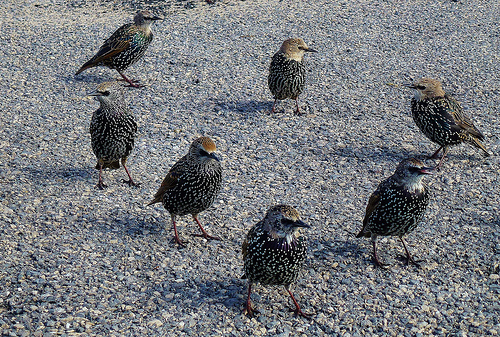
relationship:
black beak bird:
[297, 41, 318, 57] [271, 29, 327, 119]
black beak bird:
[400, 79, 430, 94] [397, 66, 491, 150]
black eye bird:
[297, 41, 318, 57] [271, 29, 327, 119]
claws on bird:
[266, 94, 308, 119] [271, 29, 327, 119]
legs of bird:
[266, 94, 308, 119] [271, 29, 327, 119]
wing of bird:
[75, 34, 121, 76] [90, 9, 174, 83]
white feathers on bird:
[254, 220, 288, 239] [235, 202, 315, 272]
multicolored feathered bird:
[91, 108, 140, 160] [82, 94, 138, 166]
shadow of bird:
[211, 97, 273, 119] [246, 21, 319, 120]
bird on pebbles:
[263, 35, 311, 111] [259, 129, 319, 167]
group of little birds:
[60, 26, 465, 269] [106, 20, 479, 131]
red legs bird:
[272, 54, 304, 87] [263, 35, 311, 111]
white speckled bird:
[381, 176, 419, 227] [360, 180, 426, 229]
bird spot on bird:
[263, 35, 311, 111] [263, 43, 311, 80]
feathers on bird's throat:
[267, 59, 313, 91] [263, 43, 311, 80]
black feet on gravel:
[264, 72, 311, 117] [241, 129, 296, 161]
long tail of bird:
[459, 120, 489, 164] [354, 91, 474, 133]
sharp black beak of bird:
[397, 82, 422, 96] [393, 66, 461, 138]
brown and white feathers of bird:
[425, 76, 457, 98] [426, 65, 485, 117]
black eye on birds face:
[400, 79, 430, 94] [409, 78, 437, 108]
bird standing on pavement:
[263, 43, 311, 80] [271, 29, 327, 119]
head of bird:
[257, 20, 328, 68] [263, 35, 311, 111]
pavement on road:
[328, 66, 379, 114] [336, 96, 377, 138]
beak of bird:
[306, 42, 329, 56] [246, 21, 319, 120]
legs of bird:
[266, 94, 308, 119] [263, 43, 311, 80]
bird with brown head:
[263, 43, 311, 80] [280, 34, 317, 57]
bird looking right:
[263, 35, 311, 111] [273, 33, 326, 66]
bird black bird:
[263, 35, 311, 111] [246, 21, 319, 120]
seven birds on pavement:
[60, 26, 465, 269] [333, 34, 383, 75]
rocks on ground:
[367, 20, 411, 52] [358, 14, 446, 42]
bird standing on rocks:
[235, 202, 316, 322] [367, 20, 411, 52]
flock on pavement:
[60, 26, 465, 269] [84, 102, 289, 217]